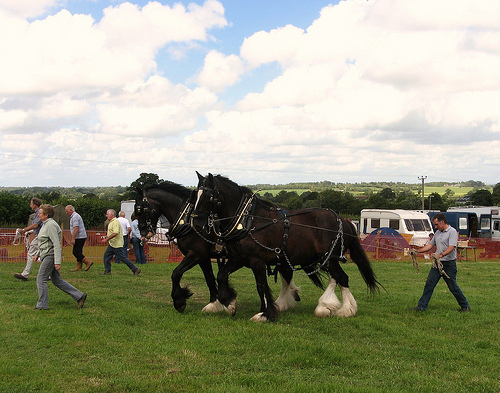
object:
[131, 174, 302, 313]
horse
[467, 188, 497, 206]
trees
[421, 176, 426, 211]
post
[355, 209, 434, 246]
car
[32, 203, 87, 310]
baseball player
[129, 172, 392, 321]
two horses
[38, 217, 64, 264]
shirt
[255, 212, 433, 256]
electric line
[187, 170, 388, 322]
horse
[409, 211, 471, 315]
man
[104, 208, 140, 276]
man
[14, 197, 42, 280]
man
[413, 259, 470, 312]
pants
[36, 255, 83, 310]
pants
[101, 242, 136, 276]
pants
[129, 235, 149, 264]
pants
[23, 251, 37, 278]
pants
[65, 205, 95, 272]
man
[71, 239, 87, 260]
pants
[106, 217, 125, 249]
shirt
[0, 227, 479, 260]
fence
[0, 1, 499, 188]
sky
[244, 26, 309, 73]
clouds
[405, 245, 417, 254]
hand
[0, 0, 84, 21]
clouds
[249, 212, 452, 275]
reigns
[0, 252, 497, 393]
grass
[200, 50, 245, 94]
clouds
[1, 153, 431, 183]
line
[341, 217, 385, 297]
tail